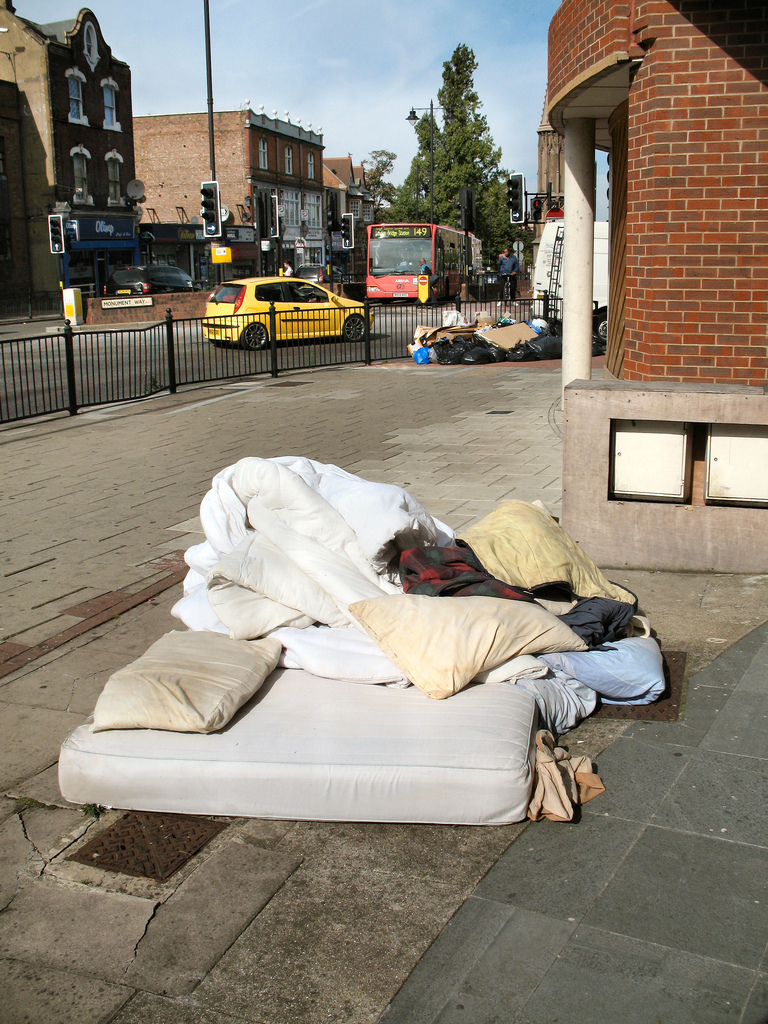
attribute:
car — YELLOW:
[198, 255, 383, 354]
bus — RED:
[359, 208, 465, 328]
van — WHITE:
[512, 198, 623, 327]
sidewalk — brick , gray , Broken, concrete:
[11, 317, 753, 1019]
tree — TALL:
[389, 32, 523, 294]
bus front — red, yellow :
[360, 201, 457, 326]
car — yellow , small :
[193, 261, 374, 355]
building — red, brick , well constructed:
[536, 4, 765, 406]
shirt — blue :
[475, 271, 501, 300]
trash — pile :
[389, 304, 618, 365]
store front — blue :
[39, 14, 159, 317]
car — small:
[201, 268, 388, 351]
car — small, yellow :
[200, 272, 378, 340]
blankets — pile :
[172, 419, 673, 709]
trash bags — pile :
[396, 289, 588, 368]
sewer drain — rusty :
[38, 793, 255, 897]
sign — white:
[97, 294, 154, 312]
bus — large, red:
[363, 220, 485, 303]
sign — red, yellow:
[418, 270, 429, 304]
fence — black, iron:
[2, 290, 560, 425]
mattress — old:
[59, 667, 539, 824]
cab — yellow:
[201, 275, 372, 349]